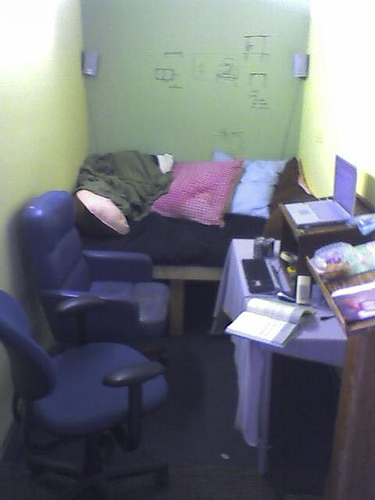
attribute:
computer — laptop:
[275, 172, 362, 227]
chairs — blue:
[23, 199, 177, 323]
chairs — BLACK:
[1, 175, 174, 478]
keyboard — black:
[242, 256, 275, 293]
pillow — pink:
[152, 159, 244, 227]